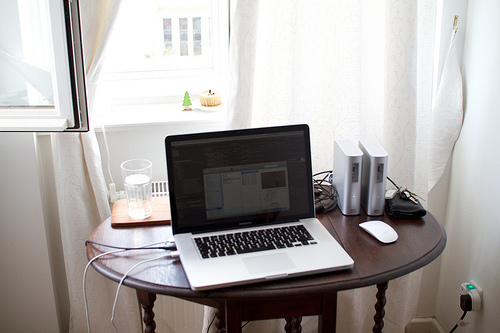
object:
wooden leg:
[219, 310, 245, 330]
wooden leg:
[138, 291, 160, 333]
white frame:
[1, 0, 76, 133]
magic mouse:
[359, 220, 399, 243]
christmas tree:
[181, 91, 193, 112]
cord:
[82, 241, 178, 333]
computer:
[164, 123, 354, 293]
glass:
[119, 158, 154, 221]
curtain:
[1, 1, 147, 333]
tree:
[182, 90, 192, 110]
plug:
[459, 293, 473, 311]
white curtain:
[293, 0, 466, 211]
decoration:
[197, 87, 224, 110]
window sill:
[91, 93, 232, 129]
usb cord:
[126, 249, 178, 276]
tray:
[109, 195, 171, 227]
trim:
[413, 313, 446, 330]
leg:
[371, 281, 389, 333]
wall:
[433, 15, 494, 257]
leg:
[282, 295, 305, 332]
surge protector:
[459, 283, 481, 311]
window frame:
[0, 2, 90, 132]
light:
[465, 283, 476, 290]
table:
[85, 197, 445, 331]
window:
[0, 0, 235, 110]